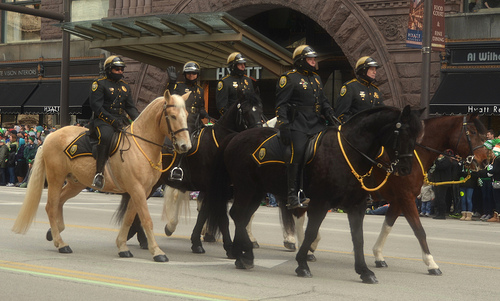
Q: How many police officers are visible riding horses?
A: Five.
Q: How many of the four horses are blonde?
A: One.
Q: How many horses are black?
A: Two.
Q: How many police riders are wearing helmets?
A: Five.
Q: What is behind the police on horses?
A: Awning of the building.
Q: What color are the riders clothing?
A: Black.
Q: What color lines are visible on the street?
A: Blue and yellow.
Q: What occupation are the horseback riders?
A: Police.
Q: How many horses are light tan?
A: 1.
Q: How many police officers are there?
A: 5.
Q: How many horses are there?
A: 5.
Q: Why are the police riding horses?
A: Parade.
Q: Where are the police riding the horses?
A: Street.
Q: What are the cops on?
A: Horses.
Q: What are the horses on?
A: The street.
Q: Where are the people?
A: On the sidewalk.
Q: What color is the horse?
A: Brown.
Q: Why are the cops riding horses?
A: Parade.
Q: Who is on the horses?
A: Cops.